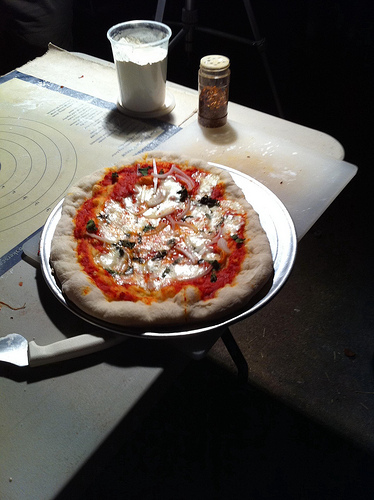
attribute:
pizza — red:
[106, 169, 239, 310]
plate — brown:
[266, 203, 297, 238]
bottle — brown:
[198, 53, 231, 128]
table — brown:
[260, 135, 317, 194]